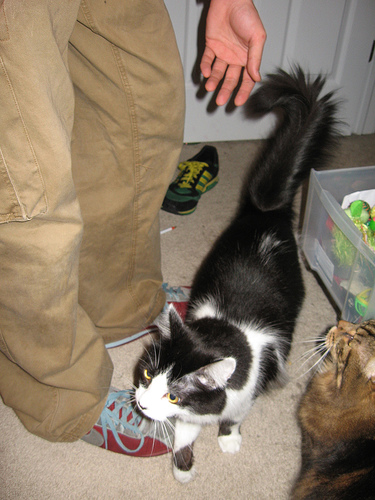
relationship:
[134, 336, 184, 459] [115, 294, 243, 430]
whiskers in face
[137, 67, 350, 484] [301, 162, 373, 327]
cat in drawer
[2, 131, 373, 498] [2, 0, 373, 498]
carpeting in room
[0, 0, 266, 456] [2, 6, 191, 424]
man wearing pants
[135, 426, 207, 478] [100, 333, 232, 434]
whiskers on face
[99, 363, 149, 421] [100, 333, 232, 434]
whiskers on face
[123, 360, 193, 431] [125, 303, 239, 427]
markings on face